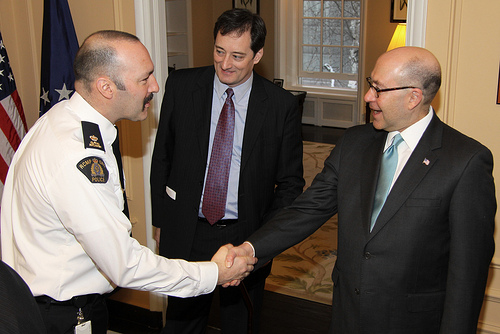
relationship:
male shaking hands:
[0, 31, 260, 331] [207, 239, 258, 287]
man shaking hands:
[304, 39, 500, 334] [207, 239, 258, 287]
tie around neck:
[203, 85, 238, 221] [210, 68, 256, 90]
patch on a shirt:
[75, 153, 109, 183] [0, 92, 217, 301]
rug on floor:
[274, 218, 331, 310] [262, 127, 353, 303]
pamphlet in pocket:
[162, 185, 179, 200] [155, 184, 178, 214]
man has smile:
[149, 5, 309, 332] [216, 66, 238, 76]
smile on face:
[216, 66, 238, 76] [212, 40, 251, 85]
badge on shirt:
[75, 154, 110, 184] [0, 92, 217, 301]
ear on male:
[249, 39, 276, 79] [0, 31, 260, 331]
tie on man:
[203, 85, 238, 221] [149, 5, 309, 332]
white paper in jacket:
[163, 184, 177, 201] [150, 61, 307, 255]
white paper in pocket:
[163, 184, 177, 201] [160, 192, 176, 216]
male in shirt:
[0, 31, 260, 331] [0, 92, 217, 301]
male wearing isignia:
[0, 31, 260, 331] [80, 112, 103, 147]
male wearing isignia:
[0, 31, 260, 331] [75, 155, 112, 188]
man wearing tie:
[304, 39, 500, 334] [354, 132, 407, 229]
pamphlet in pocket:
[162, 185, 179, 200] [159, 188, 179, 218]